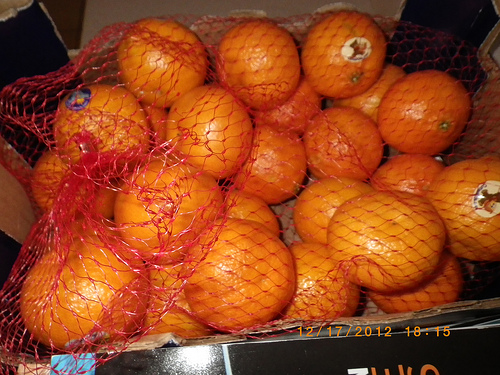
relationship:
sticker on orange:
[350, 41, 373, 65] [222, 30, 309, 101]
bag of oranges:
[4, 84, 59, 114] [128, 94, 379, 242]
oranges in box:
[128, 94, 379, 242] [166, 357, 307, 367]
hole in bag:
[89, 193, 171, 223] [4, 84, 59, 114]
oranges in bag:
[128, 94, 379, 242] [4, 84, 59, 114]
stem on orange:
[340, 73, 368, 85] [222, 30, 309, 101]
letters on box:
[364, 368, 436, 371] [166, 357, 307, 367]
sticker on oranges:
[350, 41, 373, 65] [128, 94, 379, 242]